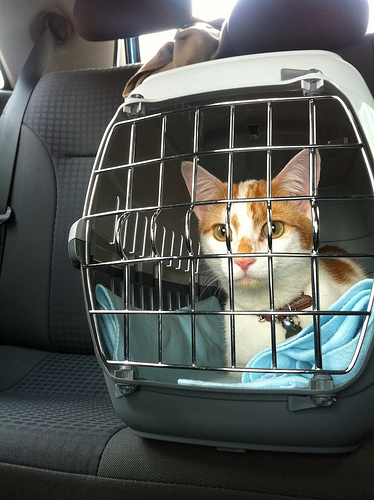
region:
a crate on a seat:
[92, 61, 358, 446]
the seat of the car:
[18, 86, 94, 491]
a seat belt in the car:
[6, 28, 26, 233]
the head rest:
[74, 0, 203, 35]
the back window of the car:
[142, 7, 236, 51]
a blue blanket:
[261, 291, 364, 388]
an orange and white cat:
[186, 152, 317, 291]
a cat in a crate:
[100, 84, 369, 404]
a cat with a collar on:
[183, 152, 314, 329]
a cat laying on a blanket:
[128, 157, 361, 390]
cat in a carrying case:
[81, 64, 370, 466]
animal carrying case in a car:
[65, 52, 366, 446]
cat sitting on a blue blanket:
[178, 275, 373, 387]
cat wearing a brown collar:
[251, 289, 312, 316]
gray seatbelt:
[0, 21, 60, 259]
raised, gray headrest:
[67, 0, 194, 43]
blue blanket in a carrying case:
[94, 284, 372, 389]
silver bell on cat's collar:
[282, 316, 293, 326]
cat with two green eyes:
[210, 218, 284, 242]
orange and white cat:
[184, 155, 360, 368]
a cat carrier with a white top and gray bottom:
[71, 53, 372, 449]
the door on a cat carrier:
[78, 93, 372, 377]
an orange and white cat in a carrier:
[176, 145, 370, 374]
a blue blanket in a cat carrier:
[97, 276, 373, 387]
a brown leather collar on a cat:
[255, 288, 314, 323]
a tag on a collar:
[278, 309, 300, 336]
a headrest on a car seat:
[71, 0, 190, 40]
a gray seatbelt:
[0, 27, 59, 272]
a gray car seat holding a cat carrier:
[0, 31, 372, 498]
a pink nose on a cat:
[232, 256, 257, 272]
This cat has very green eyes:
[262, 215, 301, 254]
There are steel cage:
[238, 300, 256, 344]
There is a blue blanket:
[325, 319, 334, 352]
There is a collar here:
[270, 298, 291, 316]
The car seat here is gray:
[53, 388, 77, 461]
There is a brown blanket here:
[163, 33, 188, 70]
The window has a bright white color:
[145, 38, 151, 50]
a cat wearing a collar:
[255, 276, 321, 335]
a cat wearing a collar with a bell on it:
[268, 296, 311, 344]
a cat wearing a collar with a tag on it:
[272, 297, 309, 345]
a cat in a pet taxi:
[68, 58, 329, 414]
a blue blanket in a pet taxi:
[247, 274, 372, 413]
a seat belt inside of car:
[0, 27, 58, 175]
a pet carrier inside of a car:
[18, 57, 348, 495]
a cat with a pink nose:
[229, 189, 265, 281]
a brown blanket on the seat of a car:
[103, 7, 231, 102]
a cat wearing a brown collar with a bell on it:
[237, 288, 321, 339]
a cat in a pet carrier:
[72, 52, 363, 423]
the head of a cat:
[159, 159, 317, 297]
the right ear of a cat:
[163, 156, 223, 223]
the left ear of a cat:
[273, 131, 345, 228]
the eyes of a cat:
[212, 220, 294, 239]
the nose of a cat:
[232, 241, 251, 270]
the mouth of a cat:
[226, 259, 271, 291]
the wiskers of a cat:
[183, 257, 233, 301]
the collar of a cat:
[248, 291, 318, 331]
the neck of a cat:
[214, 274, 305, 316]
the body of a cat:
[231, 302, 360, 369]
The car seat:
[2, 339, 370, 498]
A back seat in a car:
[7, 345, 364, 497]